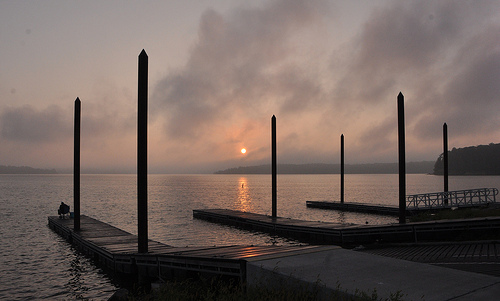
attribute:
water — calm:
[151, 179, 430, 200]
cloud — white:
[4, 97, 123, 144]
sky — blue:
[12, 9, 174, 87]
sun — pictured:
[218, 123, 275, 184]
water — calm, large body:
[3, 172, 497, 299]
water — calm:
[103, 157, 251, 254]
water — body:
[162, 171, 260, 202]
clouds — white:
[238, 21, 381, 103]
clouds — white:
[157, 68, 204, 135]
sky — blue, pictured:
[8, 6, 494, 177]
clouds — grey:
[151, 11, 307, 141]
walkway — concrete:
[249, 240, 498, 297]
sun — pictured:
[235, 141, 249, 160]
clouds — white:
[203, 25, 400, 82]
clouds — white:
[5, 101, 66, 153]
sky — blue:
[28, 27, 426, 162]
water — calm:
[35, 136, 375, 258]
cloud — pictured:
[149, 0, 324, 145]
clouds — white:
[154, 5, 312, 133]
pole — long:
[107, 60, 184, 236]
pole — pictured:
[132, 45, 169, 252]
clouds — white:
[178, 71, 204, 111]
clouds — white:
[288, 95, 310, 115]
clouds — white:
[449, 99, 479, 133]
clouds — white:
[362, 22, 404, 78]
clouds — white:
[459, 58, 488, 103]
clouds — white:
[181, 3, 399, 89]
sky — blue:
[76, 7, 156, 46]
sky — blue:
[208, 107, 256, 146]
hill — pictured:
[433, 137, 498, 187]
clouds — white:
[0, 0, 500, 170]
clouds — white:
[157, 4, 498, 142]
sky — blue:
[11, 8, 483, 136]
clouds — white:
[2, 98, 115, 144]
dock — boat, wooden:
[301, 197, 448, 224]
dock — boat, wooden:
[188, 200, 357, 247]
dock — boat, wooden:
[43, 207, 171, 280]